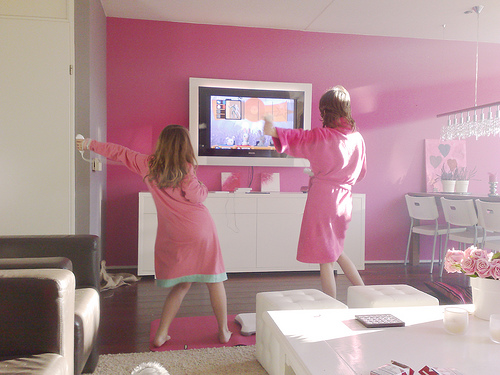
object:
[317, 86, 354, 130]
head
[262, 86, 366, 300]
woman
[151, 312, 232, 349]
foot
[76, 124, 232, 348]
girl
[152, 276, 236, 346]
leg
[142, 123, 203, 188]
head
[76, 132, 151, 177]
arm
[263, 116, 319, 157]
arm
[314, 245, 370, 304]
leg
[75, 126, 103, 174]
controller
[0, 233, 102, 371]
chair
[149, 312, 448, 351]
rug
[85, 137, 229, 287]
robe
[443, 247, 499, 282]
flowers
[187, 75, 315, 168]
tv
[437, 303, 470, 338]
glass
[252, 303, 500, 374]
table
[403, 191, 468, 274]
chair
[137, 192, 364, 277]
cabinet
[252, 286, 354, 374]
seat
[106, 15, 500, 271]
wall